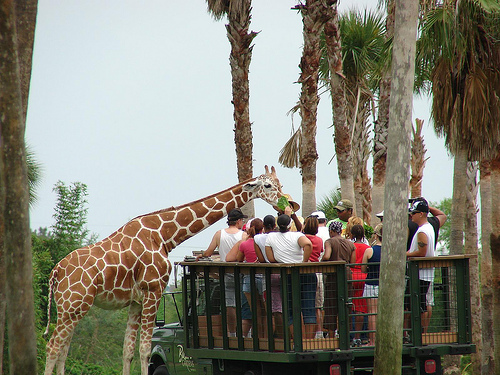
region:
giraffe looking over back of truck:
[36, 160, 288, 373]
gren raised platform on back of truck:
[177, 252, 476, 366]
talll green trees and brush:
[33, 175, 178, 370]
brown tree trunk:
[1, 2, 42, 374]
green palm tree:
[307, 4, 394, 225]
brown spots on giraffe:
[97, 243, 153, 287]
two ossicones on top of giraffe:
[257, 160, 281, 177]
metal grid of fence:
[293, 268, 342, 351]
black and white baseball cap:
[409, 197, 431, 217]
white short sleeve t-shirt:
[266, 228, 306, 263]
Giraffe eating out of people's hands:
[91, 132, 353, 324]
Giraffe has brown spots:
[105, 240, 145, 265]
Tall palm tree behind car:
[215, 41, 281, 146]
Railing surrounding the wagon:
[197, 276, 306, 345]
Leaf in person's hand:
[269, 202, 309, 224]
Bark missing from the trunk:
[382, 148, 412, 274]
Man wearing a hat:
[410, 193, 432, 245]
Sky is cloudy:
[82, 93, 203, 158]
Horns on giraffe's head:
[250, 157, 288, 176]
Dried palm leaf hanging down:
[267, 106, 316, 187]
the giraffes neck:
[166, 204, 221, 236]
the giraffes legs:
[120, 304, 164, 372]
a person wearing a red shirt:
[352, 242, 363, 259]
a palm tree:
[224, 16, 263, 156]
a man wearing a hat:
[332, 200, 350, 212]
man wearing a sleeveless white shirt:
[422, 229, 440, 244]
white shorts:
[364, 285, 377, 297]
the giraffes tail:
[41, 274, 58, 331]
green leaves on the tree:
[53, 188, 96, 242]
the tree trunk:
[0, 158, 47, 368]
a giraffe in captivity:
[44, 167, 284, 374]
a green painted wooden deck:
[175, 252, 474, 357]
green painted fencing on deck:
[178, 265, 468, 348]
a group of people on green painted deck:
[189, 192, 451, 347]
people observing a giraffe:
[37, 156, 444, 373]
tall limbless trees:
[1, 0, 496, 372]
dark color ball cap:
[407, 198, 427, 210]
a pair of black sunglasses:
[409, 209, 422, 216]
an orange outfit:
[349, 243, 367, 315]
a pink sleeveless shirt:
[241, 240, 266, 271]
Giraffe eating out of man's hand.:
[44, 161, 289, 373]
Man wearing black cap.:
[226, 206, 251, 226]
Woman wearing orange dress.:
[350, 239, 375, 319]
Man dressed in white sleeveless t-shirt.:
[406, 218, 438, 280]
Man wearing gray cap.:
[330, 196, 357, 216]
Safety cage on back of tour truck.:
[171, 254, 485, 367]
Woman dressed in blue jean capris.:
[283, 271, 324, 329]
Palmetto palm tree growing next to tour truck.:
[421, 5, 498, 372]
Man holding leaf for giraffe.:
[272, 193, 299, 217]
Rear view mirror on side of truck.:
[153, 284, 181, 332]